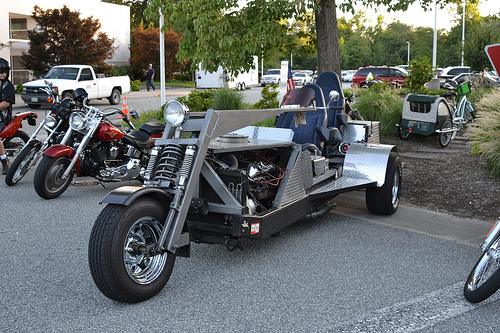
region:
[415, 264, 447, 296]
edge of a line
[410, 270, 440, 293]
par tof a raod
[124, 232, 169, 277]
par tof a rim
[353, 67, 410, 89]
a red van parked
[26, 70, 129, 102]
a white truck in the street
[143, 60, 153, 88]
a man walking down the street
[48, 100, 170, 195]
a red motorcycle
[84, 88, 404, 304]
a large motorcycle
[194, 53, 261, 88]
a large white trailer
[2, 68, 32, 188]
a person sitting on a motorcycle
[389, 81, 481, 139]
a bicycle pulling a small holder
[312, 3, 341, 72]
the trunk of a tree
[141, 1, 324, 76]
leaves hanging from the tree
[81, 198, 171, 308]
tire on the bike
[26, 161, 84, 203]
tire on the bike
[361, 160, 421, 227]
tire on the bike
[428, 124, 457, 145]
tire on the bike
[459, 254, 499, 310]
tire on the bike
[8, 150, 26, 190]
tire on the bike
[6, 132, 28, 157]
tire on the bike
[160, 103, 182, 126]
light on the bike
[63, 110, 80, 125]
light on the bike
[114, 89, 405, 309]
motorcycle on the street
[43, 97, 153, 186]
motorcycle on the street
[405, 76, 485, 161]
motorcycle on the street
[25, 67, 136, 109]
vehicle on the street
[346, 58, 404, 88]
vehicle on the street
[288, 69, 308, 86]
vehicle on the street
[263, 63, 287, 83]
vehicle on the street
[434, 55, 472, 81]
vehicle on the street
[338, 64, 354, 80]
vehicle on the street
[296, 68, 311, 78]
vehicle on the street